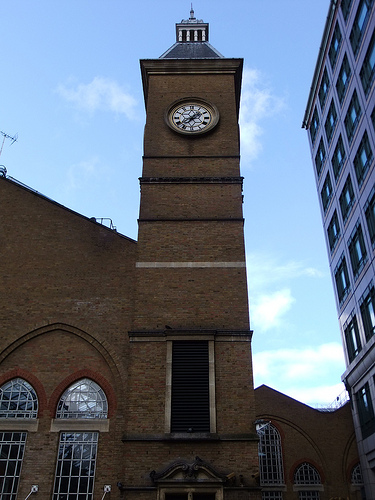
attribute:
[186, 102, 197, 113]
numeral — roman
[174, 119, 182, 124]
numeral — roman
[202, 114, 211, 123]
numeral — roman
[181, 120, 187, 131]
numeral — roman